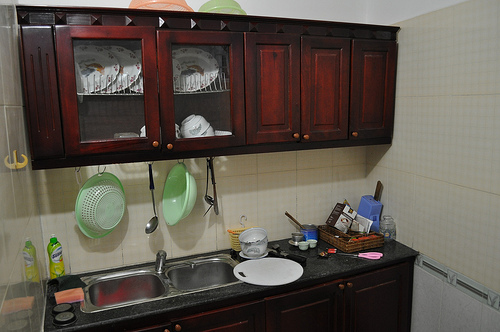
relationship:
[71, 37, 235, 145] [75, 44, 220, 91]
windows show dishes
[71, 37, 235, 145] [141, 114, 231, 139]
windows show cups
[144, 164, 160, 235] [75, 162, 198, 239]
ladle between colanders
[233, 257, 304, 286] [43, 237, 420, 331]
plate on counter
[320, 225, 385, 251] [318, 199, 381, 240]
tray has items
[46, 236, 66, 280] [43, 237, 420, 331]
bottle on counter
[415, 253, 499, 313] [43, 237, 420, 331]
tile beside counter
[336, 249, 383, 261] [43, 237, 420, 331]
scissors on counter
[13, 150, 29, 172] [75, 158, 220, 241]
hook for utensils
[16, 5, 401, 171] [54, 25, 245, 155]
cabinets have doors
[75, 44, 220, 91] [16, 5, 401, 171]
plates in cabinet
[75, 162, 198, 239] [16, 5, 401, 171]
colanders under cabinets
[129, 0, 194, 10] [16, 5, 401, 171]
bowl above cabinets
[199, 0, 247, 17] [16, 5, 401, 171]
bowl above cabinets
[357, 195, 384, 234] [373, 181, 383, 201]
block for knife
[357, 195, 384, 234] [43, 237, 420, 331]
block on counter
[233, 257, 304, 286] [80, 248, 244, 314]
plate near sinks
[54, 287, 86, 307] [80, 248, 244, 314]
sponge by sinks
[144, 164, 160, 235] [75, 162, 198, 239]
ladle near colanders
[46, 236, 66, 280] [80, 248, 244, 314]
bottle beside sinks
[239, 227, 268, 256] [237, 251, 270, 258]
bowl with saucer